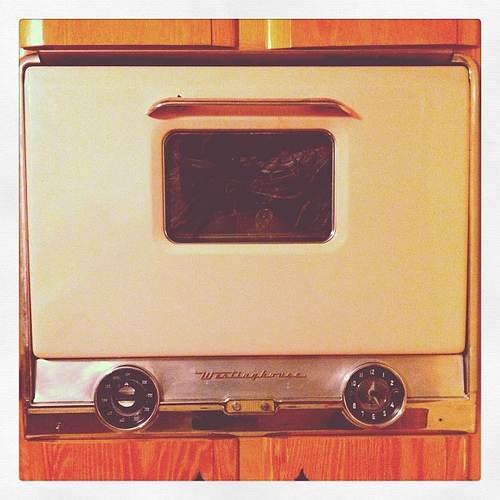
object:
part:
[167, 131, 334, 244]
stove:
[21, 50, 476, 433]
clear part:
[162, 127, 337, 247]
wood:
[21, 17, 484, 49]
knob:
[92, 363, 163, 434]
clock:
[345, 364, 405, 424]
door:
[26, 67, 465, 354]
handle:
[146, 96, 355, 117]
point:
[295, 467, 309, 481]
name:
[195, 369, 307, 382]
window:
[161, 126, 337, 245]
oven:
[22, 47, 478, 435]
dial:
[98, 368, 158, 429]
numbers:
[99, 372, 154, 425]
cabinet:
[23, 437, 482, 481]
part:
[29, 358, 473, 407]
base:
[32, 358, 471, 415]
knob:
[340, 361, 408, 430]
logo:
[195, 369, 307, 381]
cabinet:
[263, 432, 482, 483]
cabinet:
[21, 19, 240, 54]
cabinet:
[264, 14, 479, 50]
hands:
[368, 379, 380, 406]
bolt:
[233, 402, 241, 411]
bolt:
[261, 403, 269, 411]